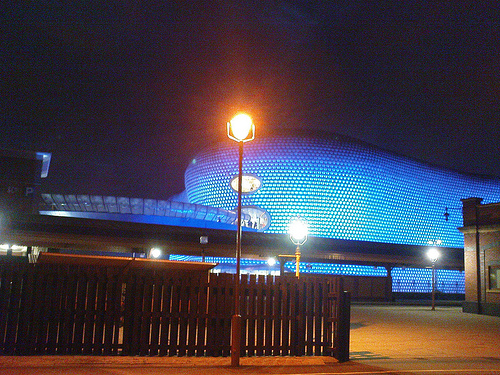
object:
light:
[229, 172, 264, 194]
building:
[166, 131, 498, 300]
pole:
[111, 267, 119, 354]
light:
[418, 173, 421, 176]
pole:
[197, 270, 209, 356]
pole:
[272, 275, 282, 354]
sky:
[1, 0, 500, 198]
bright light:
[266, 257, 276, 267]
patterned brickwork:
[181, 129, 498, 298]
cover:
[35, 192, 249, 226]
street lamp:
[221, 110, 255, 367]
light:
[354, 199, 358, 203]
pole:
[284, 218, 312, 282]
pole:
[228, 137, 245, 366]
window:
[231, 174, 264, 194]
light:
[192, 158, 197, 165]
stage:
[32, 184, 257, 231]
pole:
[305, 276, 315, 357]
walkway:
[1, 240, 497, 375]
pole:
[214, 274, 232, 353]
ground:
[328, 302, 499, 372]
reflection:
[339, 318, 491, 373]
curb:
[4, 350, 344, 373]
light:
[226, 111, 255, 142]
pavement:
[0, 303, 500, 375]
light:
[327, 203, 330, 208]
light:
[339, 186, 343, 189]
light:
[305, 185, 309, 187]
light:
[363, 220, 367, 223]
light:
[348, 235, 351, 237]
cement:
[2, 231, 112, 248]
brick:
[11, 222, 78, 231]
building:
[4, 143, 47, 217]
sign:
[20, 182, 37, 199]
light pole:
[426, 244, 447, 313]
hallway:
[33, 190, 263, 225]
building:
[456, 195, 499, 318]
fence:
[0, 269, 348, 355]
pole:
[272, 275, 280, 356]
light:
[463, 190, 466, 192]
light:
[304, 180, 308, 183]